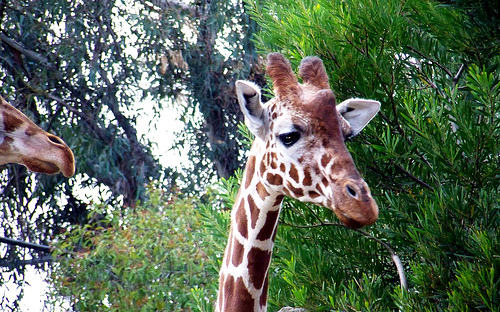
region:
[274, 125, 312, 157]
giraffe's eye is black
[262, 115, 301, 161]
giraffe's eye is black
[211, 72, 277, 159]
the ear is white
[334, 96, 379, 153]
the ear is white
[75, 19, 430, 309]
a tall giraffe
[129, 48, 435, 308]
a tall giraffe outside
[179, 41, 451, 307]
a tall giraffe that is outside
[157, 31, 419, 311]
a giraffe that is outside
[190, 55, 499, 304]
a tall giraffe standing outside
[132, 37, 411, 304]
a giraffe standing outside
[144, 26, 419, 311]
giraffe standing next to tree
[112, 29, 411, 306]
a tall giraffe standing by tree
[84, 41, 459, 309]
a tree next to giraffe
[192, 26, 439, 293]
a tree next to tall giraffe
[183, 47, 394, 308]
A giraffe in front of a tree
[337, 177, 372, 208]
The nose of the giraffe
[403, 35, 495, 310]
Trees behind the giraffe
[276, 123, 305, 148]
The right eye of the giraffe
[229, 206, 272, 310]
The giraffe has a long neck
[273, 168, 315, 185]
The giraffe has brown and white spots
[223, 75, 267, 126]
The right ear of the giraffe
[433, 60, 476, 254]
The tree has green leaves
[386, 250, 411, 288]
Branches on the tree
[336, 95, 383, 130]
The left ear of the giraffe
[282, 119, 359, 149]
the giraffe's small eyes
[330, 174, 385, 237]
the nose and mouth of the main giraffe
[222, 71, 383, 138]
the giraffes perky ears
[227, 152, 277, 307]
the giraffes long neck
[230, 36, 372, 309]
the main giraffes head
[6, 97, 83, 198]
the nose and mouth of the giraffe not seen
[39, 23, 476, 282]
the trees behind the giraffe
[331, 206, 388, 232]
the mouth of the main giraffe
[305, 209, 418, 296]
the twig by the main giraffes mouth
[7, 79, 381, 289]
two giraffe in the photo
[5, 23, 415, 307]
two giraffes standing together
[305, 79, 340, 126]
horn on giraffe's face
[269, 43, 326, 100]
two furry horns on top of giraffe's head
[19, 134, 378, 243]
mouths of two giraffes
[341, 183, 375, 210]
nostril of the giraffe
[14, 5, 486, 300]
trees behind the giraffes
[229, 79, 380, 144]
white ears of giraffe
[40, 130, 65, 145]
nostril of giraffe on left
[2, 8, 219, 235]
tree with dark green leaves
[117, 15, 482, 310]
tree with bright green leaves